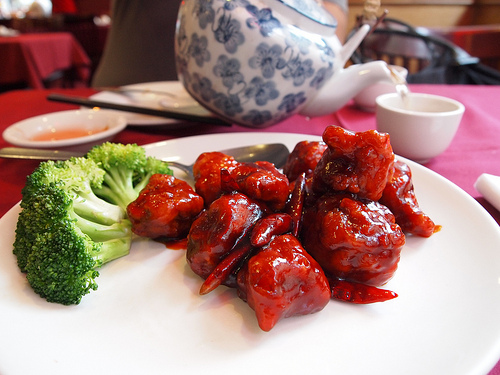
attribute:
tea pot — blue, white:
[174, 0, 392, 131]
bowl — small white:
[3, 101, 132, 154]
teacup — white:
[375, 92, 464, 163]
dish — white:
[1, 105, 127, 155]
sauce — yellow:
[26, 127, 110, 141]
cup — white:
[360, 80, 463, 173]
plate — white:
[350, 293, 452, 345]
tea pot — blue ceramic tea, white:
[173, 2, 397, 120]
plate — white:
[2, 220, 176, 373]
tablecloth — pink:
[410, 74, 495, 168]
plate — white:
[119, 267, 474, 372]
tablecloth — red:
[0, 80, 495, 198]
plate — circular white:
[3, 254, 498, 371]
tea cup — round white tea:
[374, 84, 466, 164]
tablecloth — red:
[5, 30, 97, 84]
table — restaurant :
[2, 81, 497, 155]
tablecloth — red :
[464, 95, 487, 173]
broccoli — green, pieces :
[13, 140, 175, 305]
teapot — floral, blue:
[172, 1, 405, 129]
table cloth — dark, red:
[3, 25, 88, 80]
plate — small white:
[81, 79, 221, 129]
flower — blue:
[214, 6, 244, 63]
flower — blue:
[254, 34, 282, 81]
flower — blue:
[283, 47, 311, 89]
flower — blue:
[180, 28, 212, 75]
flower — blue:
[211, 45, 254, 97]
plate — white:
[12, 125, 498, 374]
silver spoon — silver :
[3, 141, 287, 167]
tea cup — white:
[364, 80, 472, 171]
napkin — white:
[471, 170, 489, 208]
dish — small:
[3, 104, 132, 158]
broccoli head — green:
[19, 162, 101, 303]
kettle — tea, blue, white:
[191, 2, 480, 98]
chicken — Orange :
[149, 78, 439, 330]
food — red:
[131, 130, 419, 309]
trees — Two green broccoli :
[22, 155, 138, 295]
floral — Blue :
[251, 44, 284, 77]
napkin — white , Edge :
[473, 167, 485, 190]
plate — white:
[90, 138, 499, 369]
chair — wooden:
[350, 26, 447, 78]